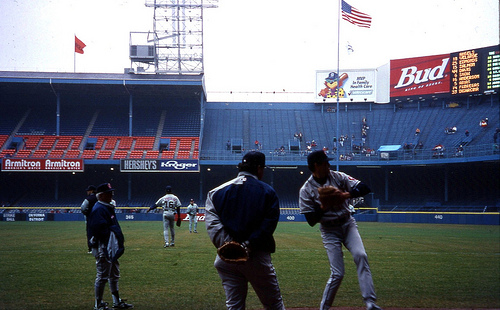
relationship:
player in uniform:
[146, 192, 181, 249] [156, 193, 181, 239]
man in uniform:
[85, 179, 169, 296] [56, 201, 140, 268]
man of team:
[88, 183, 125, 310] [78, 156, 372, 278]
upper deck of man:
[6, 87, 209, 185] [299, 150, 383, 310]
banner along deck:
[118, 159, 158, 173] [0, 133, 200, 168]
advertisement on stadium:
[317, 70, 377, 102] [1, 45, 498, 302]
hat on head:
[305, 147, 335, 178] [310, 150, 337, 186]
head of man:
[310, 150, 337, 186] [292, 148, 382, 308]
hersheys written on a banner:
[122, 154, 156, 174] [121, 158, 160, 170]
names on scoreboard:
[457, 50, 482, 102] [448, 41, 497, 91]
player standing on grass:
[147, 186, 182, 248] [4, 214, 498, 308]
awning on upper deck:
[2, 63, 203, 95] [1, 70, 206, 177]